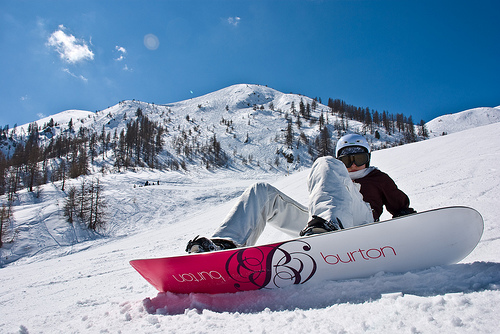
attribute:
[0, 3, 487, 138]
sky — blue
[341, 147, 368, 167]
goggles — black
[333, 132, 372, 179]
helmet — white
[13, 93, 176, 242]
trees — bare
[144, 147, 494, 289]
girl — snowboarding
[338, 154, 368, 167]
goggles — black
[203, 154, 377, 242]
pants — snow, padded, white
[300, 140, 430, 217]
jacket — black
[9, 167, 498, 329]
ground — snow-covered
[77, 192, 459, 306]
board — white, pink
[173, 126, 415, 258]
girl — seated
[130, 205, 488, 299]
board — pink, white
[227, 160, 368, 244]
pants — white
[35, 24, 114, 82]
cloud — white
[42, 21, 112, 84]
cloud — white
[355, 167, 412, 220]
jacket — black, winter, padded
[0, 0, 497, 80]
sky — clear, blue